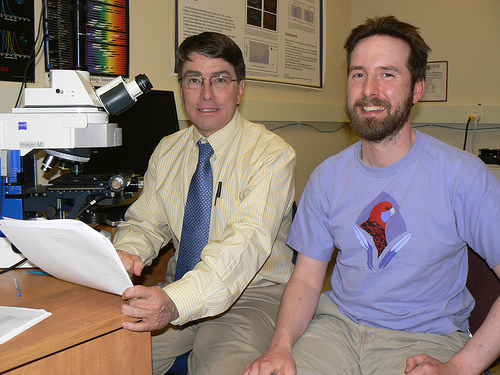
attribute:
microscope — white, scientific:
[0, 67, 154, 218]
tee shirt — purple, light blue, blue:
[286, 132, 499, 330]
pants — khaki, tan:
[291, 291, 474, 375]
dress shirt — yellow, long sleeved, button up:
[112, 109, 297, 325]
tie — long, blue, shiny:
[173, 143, 216, 279]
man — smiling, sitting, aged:
[247, 19, 499, 374]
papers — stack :
[1, 304, 51, 349]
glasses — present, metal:
[182, 74, 240, 88]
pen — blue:
[11, 274, 25, 299]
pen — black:
[214, 181, 224, 205]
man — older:
[113, 33, 298, 375]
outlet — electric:
[469, 114, 484, 124]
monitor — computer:
[91, 88, 178, 175]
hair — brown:
[345, 18, 434, 80]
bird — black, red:
[361, 200, 397, 255]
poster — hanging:
[42, 0, 131, 81]